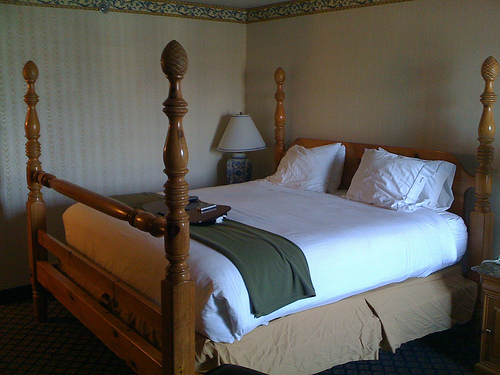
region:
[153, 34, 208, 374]
This is a tall bed holder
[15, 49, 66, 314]
This is a tall bed holder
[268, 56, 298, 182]
This is a tall bed holder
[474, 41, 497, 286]
This is a tall bed holder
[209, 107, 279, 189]
This is a tall bed side lamp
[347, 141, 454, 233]
This is a pillow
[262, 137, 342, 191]
This is a pillow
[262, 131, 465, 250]
This is a pillow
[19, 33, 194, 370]
footboard of bed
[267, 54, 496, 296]
headboard of bed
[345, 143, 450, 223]
two pillows on right side of bed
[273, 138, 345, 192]
two pillows on left side of bed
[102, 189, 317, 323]
green throw blanket on bed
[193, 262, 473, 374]
brown bed skirt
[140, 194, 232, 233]
books piled on the bed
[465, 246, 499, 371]
edge of bedside table on the right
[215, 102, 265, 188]
lamp on the left side of bed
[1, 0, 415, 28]
wall paper border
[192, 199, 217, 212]
a gray remote control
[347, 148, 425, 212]
a large white pillow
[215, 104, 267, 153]
a blue and white lamp shade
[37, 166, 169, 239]
a long brown pole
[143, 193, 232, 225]
a brown t.v. tray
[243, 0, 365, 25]
brown and blue wallpaper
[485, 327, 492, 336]
a cabinet knob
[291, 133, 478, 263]
a wooden headboard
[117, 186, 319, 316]
a long green blanket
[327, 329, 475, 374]
a blue checkered carpet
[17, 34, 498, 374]
the bed is made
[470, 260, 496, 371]
a brown wooden cabinet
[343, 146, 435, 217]
this is a white pillow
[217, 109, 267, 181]
the lamp has a white top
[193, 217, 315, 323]
a green thin sheet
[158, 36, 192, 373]
a tall stand for a bed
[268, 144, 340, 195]
a fluffy white pillow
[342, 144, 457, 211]
two pillows on the right side of the bed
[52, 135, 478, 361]
no one is on the bed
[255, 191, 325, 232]
the bedsheets are white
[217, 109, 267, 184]
Lamp in the corner is blue and white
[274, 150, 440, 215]
four white pillows on the bed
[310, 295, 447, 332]
tan sheet on bottom of bed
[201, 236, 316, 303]
green folded cover on top of bed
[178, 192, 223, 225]
items sitting on top of tray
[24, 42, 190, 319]
bed frame is made of wood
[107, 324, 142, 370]
dark marks on the wood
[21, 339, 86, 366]
carpet in room has diamond pattern on it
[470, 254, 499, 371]
small night stand next to bed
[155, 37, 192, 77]
top of post is shaped like an egg